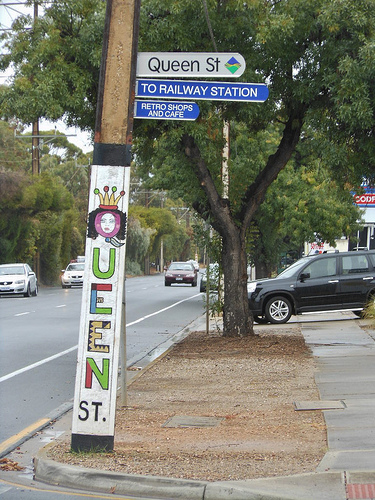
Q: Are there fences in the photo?
A: No, there are no fences.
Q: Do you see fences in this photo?
A: No, there are no fences.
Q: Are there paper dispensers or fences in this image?
A: No, there are no fences or paper dispensers.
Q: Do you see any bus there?
A: No, there are no buses.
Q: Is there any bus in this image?
A: No, there are no buses.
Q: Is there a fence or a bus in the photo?
A: No, there are no buses or fences.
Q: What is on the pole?
A: The sign is on the pole.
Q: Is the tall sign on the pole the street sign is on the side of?
A: Yes, the sign is on the pole.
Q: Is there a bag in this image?
A: No, there are no bags.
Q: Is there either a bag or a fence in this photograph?
A: No, there are no bags or fences.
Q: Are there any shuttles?
A: No, there are no shuttles.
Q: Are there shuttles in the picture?
A: No, there are no shuttles.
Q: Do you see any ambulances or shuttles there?
A: No, there are no shuttles or ambulances.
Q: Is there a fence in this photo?
A: No, there are no fences.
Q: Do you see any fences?
A: No, there are no fences.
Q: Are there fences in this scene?
A: No, there are no fences.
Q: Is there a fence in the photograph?
A: No, there are no fences.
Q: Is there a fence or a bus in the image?
A: No, there are no fences or buses.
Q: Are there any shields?
A: No, there are no shields.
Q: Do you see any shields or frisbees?
A: No, there are no shields or frisbees.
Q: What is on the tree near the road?
A: The leaves are on the tree.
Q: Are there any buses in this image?
A: No, there are no buses.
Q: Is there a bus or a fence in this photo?
A: No, there are no buses or fences.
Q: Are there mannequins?
A: No, there are no mannequins.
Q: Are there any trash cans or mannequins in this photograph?
A: No, there are no mannequins or trash cans.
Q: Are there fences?
A: No, there are no fences.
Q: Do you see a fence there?
A: No, there are no fences.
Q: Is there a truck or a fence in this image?
A: No, there are no fences or trucks.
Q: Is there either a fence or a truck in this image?
A: No, there are no fences or trucks.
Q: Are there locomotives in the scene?
A: No, there are no locomotives.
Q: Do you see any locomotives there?
A: No, there are no locomotives.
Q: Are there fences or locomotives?
A: No, there are no locomotives or fences.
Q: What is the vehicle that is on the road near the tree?
A: The vehicle is a car.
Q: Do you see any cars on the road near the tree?
A: Yes, there is a car on the road.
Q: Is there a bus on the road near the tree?
A: No, there is a car on the road.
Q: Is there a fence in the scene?
A: No, there are no fences.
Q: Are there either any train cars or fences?
A: No, there are no fences or train cars.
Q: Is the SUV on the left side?
A: No, the SUV is on the right of the image.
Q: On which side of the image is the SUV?
A: The SUV is on the right of the image.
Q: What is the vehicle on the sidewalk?
A: The vehicle is a SUV.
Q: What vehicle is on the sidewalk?
A: The vehicle is a SUV.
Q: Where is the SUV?
A: The SUV is on the sidewalk.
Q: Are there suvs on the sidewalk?
A: Yes, there is a SUV on the sidewalk.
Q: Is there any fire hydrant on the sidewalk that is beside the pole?
A: No, there is a SUV on the sidewalk.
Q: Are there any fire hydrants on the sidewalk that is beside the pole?
A: No, there is a SUV on the sidewalk.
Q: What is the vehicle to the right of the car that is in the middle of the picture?
A: The vehicle is a SUV.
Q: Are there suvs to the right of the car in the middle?
A: Yes, there is a SUV to the right of the car.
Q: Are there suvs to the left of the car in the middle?
A: No, the SUV is to the right of the car.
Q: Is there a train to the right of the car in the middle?
A: No, there is a SUV to the right of the car.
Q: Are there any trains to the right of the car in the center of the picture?
A: No, there is a SUV to the right of the car.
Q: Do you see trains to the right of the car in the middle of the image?
A: No, there is a SUV to the right of the car.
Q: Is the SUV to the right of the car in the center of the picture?
A: Yes, the SUV is to the right of the car.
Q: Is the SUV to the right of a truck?
A: No, the SUV is to the right of the car.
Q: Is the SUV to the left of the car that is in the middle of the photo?
A: No, the SUV is to the right of the car.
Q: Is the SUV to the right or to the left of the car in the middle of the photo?
A: The SUV is to the right of the car.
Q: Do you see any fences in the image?
A: No, there are no fences.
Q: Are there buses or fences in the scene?
A: No, there are no fences or buses.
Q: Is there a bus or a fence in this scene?
A: No, there are no fences or buses.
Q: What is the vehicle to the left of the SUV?
A: The vehicle is a car.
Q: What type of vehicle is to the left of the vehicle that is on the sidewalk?
A: The vehicle is a car.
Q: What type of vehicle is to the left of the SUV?
A: The vehicle is a car.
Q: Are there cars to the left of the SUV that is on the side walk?
A: Yes, there is a car to the left of the SUV.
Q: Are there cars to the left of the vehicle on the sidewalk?
A: Yes, there is a car to the left of the SUV.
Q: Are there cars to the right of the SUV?
A: No, the car is to the left of the SUV.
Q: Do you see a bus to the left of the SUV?
A: No, there is a car to the left of the SUV.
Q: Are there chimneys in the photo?
A: No, there are no chimneys.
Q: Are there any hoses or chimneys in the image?
A: No, there are no chimneys or hoses.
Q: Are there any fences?
A: No, there are no fences.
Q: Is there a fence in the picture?
A: No, there are no fences.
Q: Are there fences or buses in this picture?
A: No, there are no fences or buses.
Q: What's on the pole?
A: The sign is on the pole.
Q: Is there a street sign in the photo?
A: Yes, there is a street sign.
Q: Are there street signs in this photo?
A: Yes, there is a street sign.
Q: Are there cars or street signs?
A: Yes, there is a street sign.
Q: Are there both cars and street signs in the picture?
A: Yes, there are both a street sign and a car.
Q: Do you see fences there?
A: No, there are no fences.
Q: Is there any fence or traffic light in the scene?
A: No, there are no fences or traffic lights.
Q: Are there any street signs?
A: Yes, there is a street sign.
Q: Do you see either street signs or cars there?
A: Yes, there is a street sign.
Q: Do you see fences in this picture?
A: No, there are no fences.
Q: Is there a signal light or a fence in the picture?
A: No, there are no fences or traffic lights.